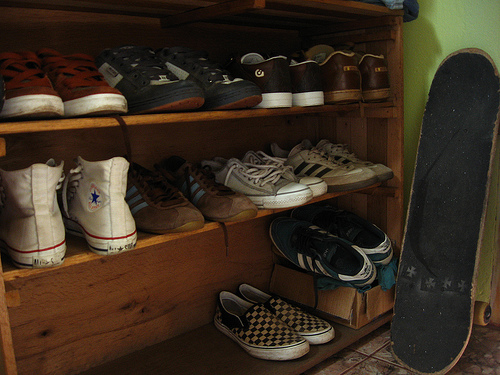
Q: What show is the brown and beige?
A: The checkered one.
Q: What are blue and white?
A: The shoes.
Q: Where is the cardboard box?
A: Under the shoes.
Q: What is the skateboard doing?
A: Learning on a wall.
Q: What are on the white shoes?
A: A blue star.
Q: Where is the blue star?
A: On the white shoes.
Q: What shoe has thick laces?
A: The red shoes.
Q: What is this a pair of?
A: Black and white shoes.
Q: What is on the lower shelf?
A: A black and white checkered shoe.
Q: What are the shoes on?
A: A brown wooden shelf.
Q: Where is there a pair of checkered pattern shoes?
A: On the lower shelf.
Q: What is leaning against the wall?
A: A skateboard with black decking tape.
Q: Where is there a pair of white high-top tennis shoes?
A: On the middle shelf.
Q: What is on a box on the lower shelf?
A: A pair of blue and white tennis shoes.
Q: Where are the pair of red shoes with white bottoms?
A: Top shelf.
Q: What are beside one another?
A: Two pairs of brown shoes.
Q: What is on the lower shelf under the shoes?
A: An old small cardboard box.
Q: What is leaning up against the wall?
A: Skateboard.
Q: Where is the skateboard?
A: Against the wall.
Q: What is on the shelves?
A: Shoes.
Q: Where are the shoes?
A: On the shelf.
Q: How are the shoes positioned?
A: In rows.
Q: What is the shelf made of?
A: Wood.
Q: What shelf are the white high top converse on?
A: The second shelf.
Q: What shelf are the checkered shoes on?
A: Bottom shelf.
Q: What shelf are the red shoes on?
A: Top shelf.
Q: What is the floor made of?
A: Tile.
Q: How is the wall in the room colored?
A: Bright green.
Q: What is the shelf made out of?
A: Wood.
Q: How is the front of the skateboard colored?
A: Black.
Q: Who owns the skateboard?
A: A skateboarder.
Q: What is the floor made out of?
A: Tiles.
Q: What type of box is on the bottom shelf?
A: Cardboard.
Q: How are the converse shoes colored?
A: Red, white, and blue.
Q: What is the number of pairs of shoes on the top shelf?
A: Four.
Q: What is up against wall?
A: Skateboard.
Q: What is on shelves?
A: Shoes.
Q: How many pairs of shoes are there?
A: Ten.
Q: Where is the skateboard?
A: Against the wall.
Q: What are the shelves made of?
A: Wood.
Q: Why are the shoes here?
A: It's a shoe storage shelf.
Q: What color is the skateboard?
A: Black.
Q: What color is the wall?
A: Lime green.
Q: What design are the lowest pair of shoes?
A: Checkerboard.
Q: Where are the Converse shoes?
A: On the middle shelf.